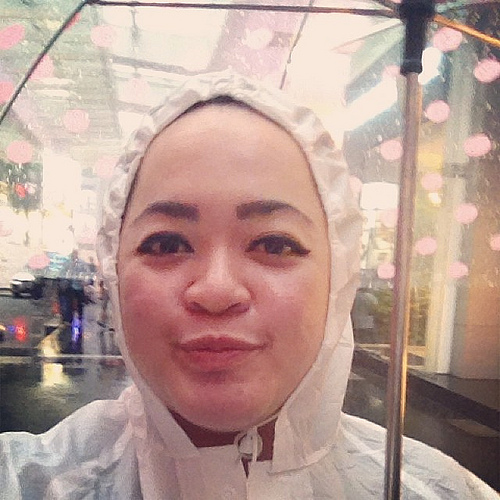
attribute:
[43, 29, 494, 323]
umbrella — pink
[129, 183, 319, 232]
eyebrowns — manicured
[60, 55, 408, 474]
woman — young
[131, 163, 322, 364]
face — selfie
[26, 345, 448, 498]
poncho — white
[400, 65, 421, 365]
pole — metal, silver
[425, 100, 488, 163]
polka dots — pink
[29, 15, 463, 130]
weather — rainy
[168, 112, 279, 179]
forehead — high, bare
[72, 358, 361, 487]
hood — white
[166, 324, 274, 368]
lips — pursed, red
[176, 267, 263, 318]
nose — pudgy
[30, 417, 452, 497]
raincoat — white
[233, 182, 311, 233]
eyebrow — groomed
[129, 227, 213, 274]
eye — brown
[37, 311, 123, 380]
ground — wet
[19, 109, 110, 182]
spots — pink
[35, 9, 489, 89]
day — rainy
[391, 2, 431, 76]
knob — black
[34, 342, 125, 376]
lines — white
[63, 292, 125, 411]
road — wet, grey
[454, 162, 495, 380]
wall — brown, white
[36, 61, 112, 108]
light — purple